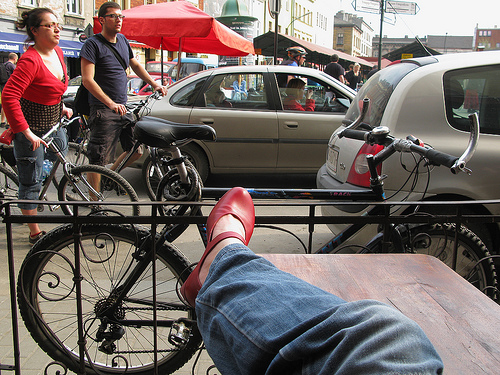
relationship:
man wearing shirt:
[70, 1, 165, 211] [77, 32, 134, 112]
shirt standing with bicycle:
[77, 32, 134, 112] [71, 87, 204, 204]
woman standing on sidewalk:
[5, 6, 75, 141] [10, 196, 194, 261]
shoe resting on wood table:
[172, 183, 262, 315] [252, 252, 500, 375]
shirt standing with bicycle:
[1, 36, 114, 141] [2, 113, 139, 228]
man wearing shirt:
[75, 1, 169, 219] [319, 61, 344, 78]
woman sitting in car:
[279, 72, 317, 109] [110, 52, 377, 168]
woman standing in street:
[0, 6, 74, 252] [1, 187, 322, 269]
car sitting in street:
[124, 64, 356, 184] [0, 149, 335, 252]